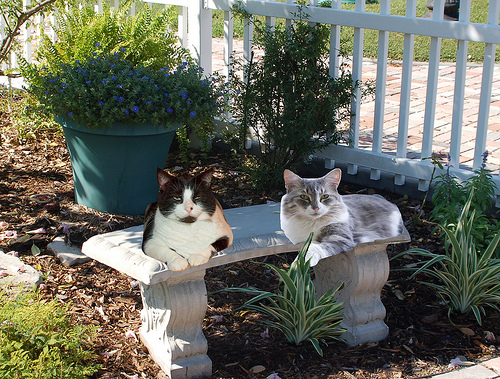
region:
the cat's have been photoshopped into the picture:
[132, 151, 412, 267]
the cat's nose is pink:
[177, 195, 198, 225]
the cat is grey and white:
[268, 161, 413, 276]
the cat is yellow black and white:
[133, 155, 235, 293]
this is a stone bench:
[72, 182, 413, 368]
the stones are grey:
[2, 230, 85, 290]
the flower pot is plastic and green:
[35, 110, 176, 230]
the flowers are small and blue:
[25, 37, 220, 140]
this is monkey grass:
[390, 170, 498, 336]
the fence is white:
[0, 0, 499, 217]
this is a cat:
[278, 170, 401, 253]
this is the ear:
[276, 162, 305, 185]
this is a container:
[86, 144, 124, 200]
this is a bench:
[242, 185, 270, 261]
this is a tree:
[247, 37, 333, 143]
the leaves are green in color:
[266, 35, 311, 75]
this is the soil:
[377, 311, 439, 361]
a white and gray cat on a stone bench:
[278, 170, 407, 263]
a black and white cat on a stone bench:
[141, 168, 235, 271]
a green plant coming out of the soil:
[209, 233, 349, 358]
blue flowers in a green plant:
[38, 38, 209, 121]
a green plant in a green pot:
[21, 2, 221, 219]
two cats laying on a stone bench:
[140, 165, 407, 270]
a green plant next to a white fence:
[229, 0, 381, 199]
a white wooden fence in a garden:
[0, 0, 499, 211]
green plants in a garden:
[2, 0, 498, 375]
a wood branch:
[0, 0, 62, 82]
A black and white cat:
[139, 163, 234, 273]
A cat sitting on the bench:
[275, 166, 415, 265]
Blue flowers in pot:
[64, 62, 208, 122]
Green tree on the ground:
[229, 10, 379, 167]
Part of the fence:
[374, 20, 437, 125]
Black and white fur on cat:
[146, 215, 171, 240]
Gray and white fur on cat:
[353, 208, 398, 231]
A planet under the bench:
[201, 230, 353, 352]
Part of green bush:
[16, 316, 49, 353]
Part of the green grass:
[363, 29, 377, 56]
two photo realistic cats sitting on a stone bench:
[1, 1, 498, 371]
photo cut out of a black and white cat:
[136, 159, 239, 272]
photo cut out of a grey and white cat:
[279, 167, 407, 267]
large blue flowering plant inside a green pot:
[19, 5, 211, 217]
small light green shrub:
[3, 293, 103, 376]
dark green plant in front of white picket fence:
[223, 1, 493, 168]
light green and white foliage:
[406, 188, 497, 326]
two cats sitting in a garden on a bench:
[1, 2, 495, 377]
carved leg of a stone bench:
[134, 282, 222, 377]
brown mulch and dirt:
[7, 138, 63, 190]